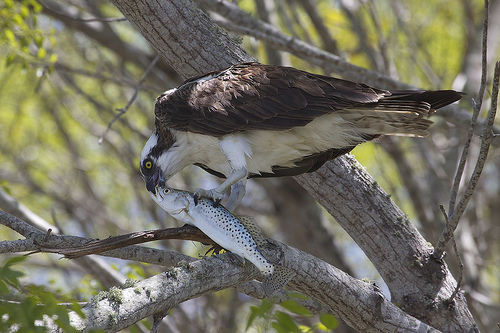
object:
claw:
[194, 194, 198, 207]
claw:
[213, 198, 220, 208]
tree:
[0, 0, 500, 333]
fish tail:
[261, 264, 296, 298]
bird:
[138, 62, 466, 209]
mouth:
[153, 169, 159, 194]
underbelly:
[200, 121, 330, 175]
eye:
[143, 158, 153, 168]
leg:
[216, 136, 255, 190]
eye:
[163, 188, 171, 194]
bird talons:
[193, 188, 225, 208]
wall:
[252, 192, 313, 212]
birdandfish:
[138, 125, 193, 226]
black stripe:
[147, 117, 177, 159]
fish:
[148, 186, 296, 298]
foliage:
[0, 256, 85, 333]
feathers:
[187, 62, 392, 131]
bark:
[363, 215, 406, 248]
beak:
[146, 168, 166, 194]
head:
[139, 149, 184, 194]